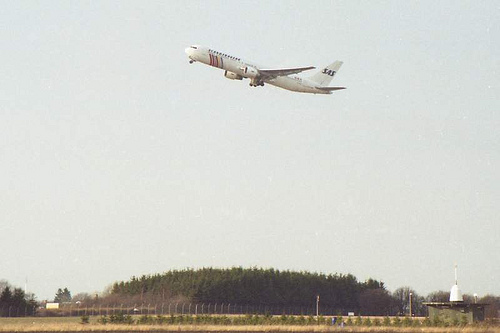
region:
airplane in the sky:
[174, 35, 362, 105]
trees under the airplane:
[101, 261, 411, 313]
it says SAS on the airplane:
[316, 58, 346, 85]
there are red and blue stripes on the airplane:
[197, 39, 234, 94]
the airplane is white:
[171, 24, 363, 116]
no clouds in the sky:
[7, 29, 160, 177]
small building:
[43, 288, 75, 323]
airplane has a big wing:
[261, 65, 318, 88]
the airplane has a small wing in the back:
[313, 78, 354, 100]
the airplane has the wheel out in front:
[181, 43, 213, 72]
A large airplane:
[174, 25, 362, 119]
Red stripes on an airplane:
[208, 52, 217, 70]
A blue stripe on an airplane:
[216, 53, 226, 70]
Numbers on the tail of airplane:
[314, 53, 342, 89]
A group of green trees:
[125, 263, 372, 303]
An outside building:
[420, 284, 487, 327]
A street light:
[310, 288, 330, 321]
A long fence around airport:
[67, 290, 353, 321]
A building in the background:
[33, 293, 75, 310]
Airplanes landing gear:
[246, 68, 275, 94]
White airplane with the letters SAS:
[177, 39, 350, 100]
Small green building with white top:
[423, 262, 489, 327]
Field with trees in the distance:
[8, 260, 496, 330]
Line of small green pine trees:
[71, 306, 486, 331]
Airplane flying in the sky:
[3, 9, 493, 264]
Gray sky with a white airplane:
[6, 6, 495, 298]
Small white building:
[42, 291, 66, 319]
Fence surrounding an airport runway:
[4, 290, 499, 331]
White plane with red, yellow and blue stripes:
[183, 38, 349, 100]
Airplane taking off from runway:
[8, 10, 497, 329]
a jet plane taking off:
[174, 24, 366, 131]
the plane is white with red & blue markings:
[170, 40, 359, 102]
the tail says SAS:
[169, 38, 371, 104]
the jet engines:
[216, 64, 256, 89]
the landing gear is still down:
[183, 57, 269, 98]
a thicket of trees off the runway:
[112, 268, 410, 319]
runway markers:
[418, 258, 490, 328]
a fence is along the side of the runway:
[59, 302, 300, 323]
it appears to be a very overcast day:
[122, 141, 419, 229]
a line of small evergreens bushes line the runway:
[80, 313, 430, 330]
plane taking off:
[182, 38, 332, 110]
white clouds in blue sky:
[17, 23, 74, 78]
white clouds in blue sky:
[88, 36, 133, 113]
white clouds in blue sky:
[91, 170, 146, 207]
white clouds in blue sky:
[150, 130, 242, 187]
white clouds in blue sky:
[224, 155, 321, 232]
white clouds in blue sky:
[303, 169, 413, 252]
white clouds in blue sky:
[368, 25, 415, 105]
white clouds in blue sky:
[65, 171, 128, 241]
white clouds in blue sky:
[104, 137, 151, 192]